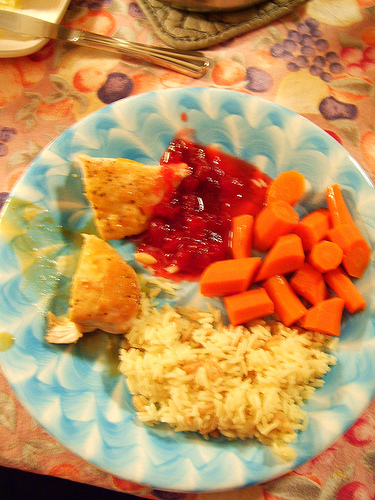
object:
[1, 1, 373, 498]
tablecloth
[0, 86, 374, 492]
plate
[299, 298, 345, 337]
carrots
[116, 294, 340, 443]
rice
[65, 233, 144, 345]
chicken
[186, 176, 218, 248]
cherries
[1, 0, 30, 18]
butter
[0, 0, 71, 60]
dish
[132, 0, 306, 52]
potholder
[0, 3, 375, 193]
print